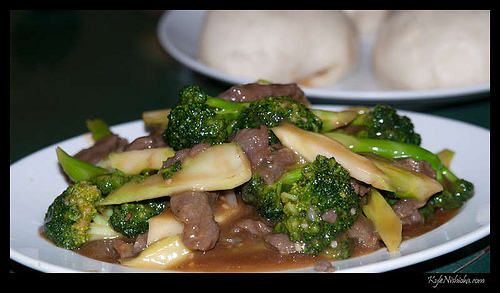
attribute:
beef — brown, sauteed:
[170, 191, 221, 252]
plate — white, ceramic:
[9, 103, 490, 273]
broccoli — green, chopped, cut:
[271, 156, 374, 253]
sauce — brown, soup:
[199, 235, 297, 272]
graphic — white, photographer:
[428, 274, 485, 292]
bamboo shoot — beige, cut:
[273, 121, 396, 197]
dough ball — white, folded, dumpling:
[194, 13, 361, 84]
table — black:
[9, 12, 498, 170]